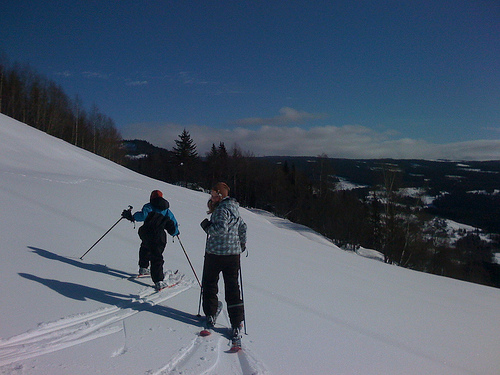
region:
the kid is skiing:
[88, 178, 213, 308]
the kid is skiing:
[36, 128, 208, 328]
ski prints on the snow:
[20, 285, 127, 370]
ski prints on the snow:
[132, 288, 242, 353]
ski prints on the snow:
[149, 320, 247, 372]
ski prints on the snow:
[149, 290, 283, 373]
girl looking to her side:
[182, 178, 272, 360]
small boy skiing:
[91, 174, 198, 293]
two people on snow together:
[70, 165, 248, 359]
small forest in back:
[0, 70, 143, 150]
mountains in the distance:
[355, 164, 485, 231]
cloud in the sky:
[231, 98, 328, 135]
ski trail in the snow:
[33, 290, 148, 364]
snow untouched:
[283, 290, 378, 346]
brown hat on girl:
[204, 182, 236, 202]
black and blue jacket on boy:
[121, 205, 188, 255]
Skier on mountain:
[199, 178, 251, 355]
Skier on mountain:
[120, 188, 180, 293]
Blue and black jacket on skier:
[121, 200, 181, 249]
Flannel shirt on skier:
[206, 198, 249, 257]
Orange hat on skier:
[148, 187, 163, 199]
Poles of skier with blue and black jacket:
[78, 204, 200, 299]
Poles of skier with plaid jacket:
[196, 218, 253, 334]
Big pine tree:
[170, 127, 200, 187]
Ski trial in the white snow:
[2, 270, 194, 366]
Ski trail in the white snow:
[156, 327, 259, 373]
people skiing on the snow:
[60, 133, 350, 369]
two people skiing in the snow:
[94, 133, 278, 373]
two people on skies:
[89, 139, 435, 371]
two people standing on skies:
[126, 143, 396, 365]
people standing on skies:
[77, 133, 298, 362]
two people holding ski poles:
[98, 148, 371, 373]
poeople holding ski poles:
[48, 130, 383, 374]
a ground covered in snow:
[49, 122, 381, 374]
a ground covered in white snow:
[17, 129, 300, 368]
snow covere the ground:
[62, 136, 427, 374]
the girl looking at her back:
[181, 173, 284, 365]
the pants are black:
[179, 246, 248, 301]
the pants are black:
[129, 214, 175, 280]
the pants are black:
[184, 243, 269, 345]